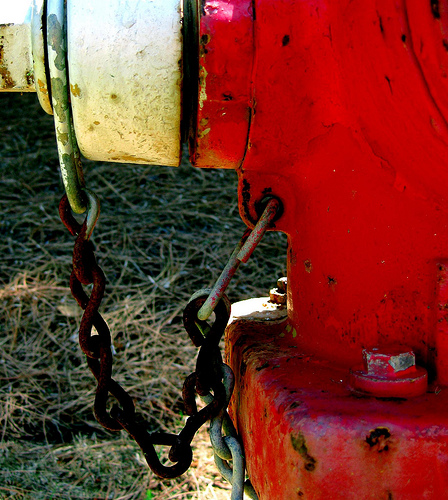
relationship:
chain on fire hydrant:
[47, 186, 282, 489] [1, 0, 446, 499]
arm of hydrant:
[2, 0, 184, 164] [1, 1, 445, 497]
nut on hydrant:
[347, 343, 427, 399] [1, 1, 445, 497]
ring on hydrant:
[44, 0, 95, 221] [1, 1, 445, 497]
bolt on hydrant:
[268, 275, 288, 305] [1, 1, 445, 497]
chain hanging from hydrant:
[51, 182, 257, 489] [194, 5, 438, 485]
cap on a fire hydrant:
[344, 343, 429, 401] [1, 1, 445, 497]